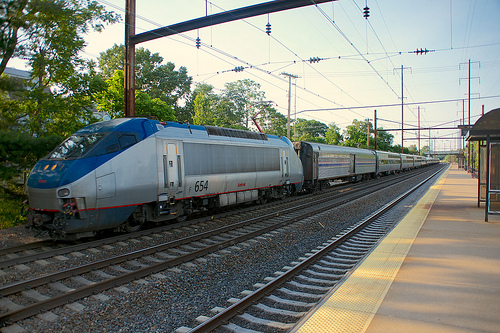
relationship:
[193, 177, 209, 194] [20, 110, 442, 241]
numbers on train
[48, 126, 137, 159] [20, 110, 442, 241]
windshield on train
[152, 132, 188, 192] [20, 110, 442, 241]
door on train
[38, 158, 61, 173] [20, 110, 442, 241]
lights on train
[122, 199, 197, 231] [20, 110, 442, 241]
wheels on train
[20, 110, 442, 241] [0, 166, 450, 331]
train on tracks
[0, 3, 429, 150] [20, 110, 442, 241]
trees near train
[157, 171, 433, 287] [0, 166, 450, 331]
gravel between tracks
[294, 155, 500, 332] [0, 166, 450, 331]
platform near tracks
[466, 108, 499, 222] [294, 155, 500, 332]
shelter on platform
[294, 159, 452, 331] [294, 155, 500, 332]
tile on platform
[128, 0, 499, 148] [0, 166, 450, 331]
wires above tracks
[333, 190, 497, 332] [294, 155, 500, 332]
shadow on platform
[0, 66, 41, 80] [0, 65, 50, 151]
roof on building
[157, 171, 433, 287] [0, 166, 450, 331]
gravel on tracks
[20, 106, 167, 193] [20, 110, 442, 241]
slope on train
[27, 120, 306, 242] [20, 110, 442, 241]
car on train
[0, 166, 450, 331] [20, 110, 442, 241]
tracks under train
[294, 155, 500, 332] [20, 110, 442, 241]
platform near train